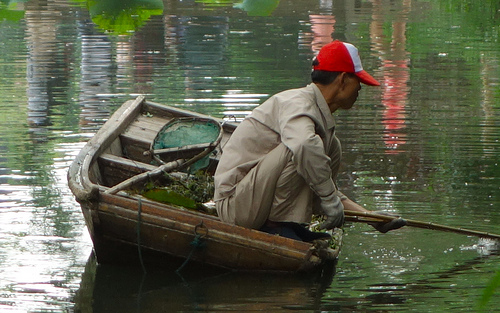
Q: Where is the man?
A: On the boat.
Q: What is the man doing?
A: Fishing.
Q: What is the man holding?
A: A rod.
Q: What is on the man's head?
A: A hat.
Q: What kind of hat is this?
A: A baseball cap.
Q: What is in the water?
A: Boat.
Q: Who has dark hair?
A: The man.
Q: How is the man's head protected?
A: A cap.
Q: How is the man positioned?
A: Sitting.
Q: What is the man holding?
A: Fishing pole.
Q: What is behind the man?
A: Fishing net.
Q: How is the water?
A: Calm.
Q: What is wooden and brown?
A: Boat.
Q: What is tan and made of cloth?
A: Clothing.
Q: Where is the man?
A: In a boat.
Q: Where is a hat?
A: On man's head.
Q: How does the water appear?
A: Murky.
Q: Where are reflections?
A: On the water.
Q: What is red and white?
A: A hat.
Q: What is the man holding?
A: An oar.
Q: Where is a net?
A: In the boat.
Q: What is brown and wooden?
A: The boat.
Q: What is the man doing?
A: Fishing.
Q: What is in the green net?
A: Wooden stick.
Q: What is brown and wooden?
A: Boat.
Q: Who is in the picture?
A: A man.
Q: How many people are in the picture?
A: One.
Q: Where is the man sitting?
A: In a boat.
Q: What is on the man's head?
A: A hat.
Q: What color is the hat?
A: Red.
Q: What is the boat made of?
A: Wood.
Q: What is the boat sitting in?
A: Water.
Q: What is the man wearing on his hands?
A: Gloves.